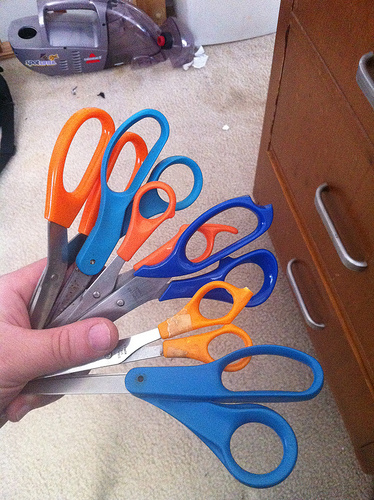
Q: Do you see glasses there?
A: No, there are no glasses.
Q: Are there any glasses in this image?
A: No, there are no glasses.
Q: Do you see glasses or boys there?
A: No, there are no glasses or boys.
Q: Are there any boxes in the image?
A: No, there are no boxes.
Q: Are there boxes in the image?
A: No, there are no boxes.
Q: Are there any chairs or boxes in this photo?
A: No, there are no boxes or chairs.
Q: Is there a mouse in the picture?
A: No, there are no computer mice.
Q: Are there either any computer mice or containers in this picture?
A: No, there are no computer mice or containers.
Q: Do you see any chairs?
A: No, there are no chairs.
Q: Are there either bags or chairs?
A: No, there are no chairs or bags.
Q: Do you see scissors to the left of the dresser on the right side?
A: Yes, there are scissors to the left of the dresser.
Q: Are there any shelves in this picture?
A: No, there are no shelves.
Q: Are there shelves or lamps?
A: No, there are no shelves or lamps.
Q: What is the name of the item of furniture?
A: The piece of furniture is a dresser.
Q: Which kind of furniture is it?
A: The piece of furniture is a dresser.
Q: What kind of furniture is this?
A: This is a dresser.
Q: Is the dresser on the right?
A: Yes, the dresser is on the right of the image.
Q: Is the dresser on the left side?
A: No, the dresser is on the right of the image.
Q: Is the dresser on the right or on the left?
A: The dresser is on the right of the image.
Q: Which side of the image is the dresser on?
A: The dresser is on the right of the image.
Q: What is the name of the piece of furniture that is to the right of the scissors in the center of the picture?
A: The piece of furniture is a dresser.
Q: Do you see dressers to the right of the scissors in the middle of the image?
A: Yes, there is a dresser to the right of the scissors.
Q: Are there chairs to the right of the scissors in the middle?
A: No, there is a dresser to the right of the scissors.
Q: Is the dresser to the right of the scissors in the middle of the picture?
A: Yes, the dresser is to the right of the scissors.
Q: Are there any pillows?
A: No, there are no pillows.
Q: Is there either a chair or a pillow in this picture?
A: No, there are no pillows or chairs.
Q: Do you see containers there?
A: No, there are no containers.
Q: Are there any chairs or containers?
A: No, there are no containers or chairs.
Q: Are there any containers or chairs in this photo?
A: No, there are no containers or chairs.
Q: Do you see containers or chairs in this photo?
A: No, there are no containers or chairs.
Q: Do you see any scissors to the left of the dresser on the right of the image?
A: Yes, there are scissors to the left of the dresser.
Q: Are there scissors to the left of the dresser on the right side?
A: Yes, there are scissors to the left of the dresser.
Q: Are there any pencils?
A: No, there are no pencils.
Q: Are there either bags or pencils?
A: No, there are no pencils or bags.